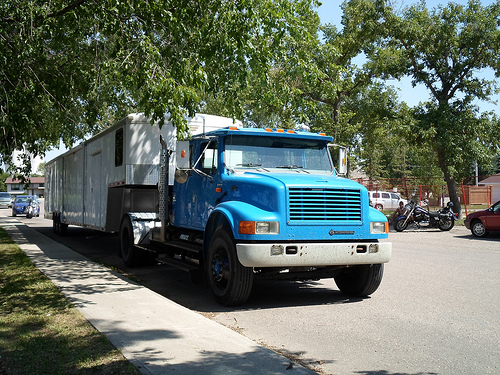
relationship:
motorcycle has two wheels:
[388, 181, 460, 238] [391, 210, 456, 233]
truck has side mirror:
[37, 109, 403, 313] [327, 140, 355, 178]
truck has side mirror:
[37, 109, 403, 313] [173, 136, 213, 180]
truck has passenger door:
[37, 109, 403, 313] [187, 139, 218, 231]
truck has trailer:
[37, 109, 403, 313] [41, 107, 252, 268]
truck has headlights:
[37, 109, 403, 313] [255, 216, 385, 239]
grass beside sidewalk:
[0, 225, 145, 375] [1, 227, 320, 375]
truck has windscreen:
[37, 109, 403, 313] [224, 134, 333, 173]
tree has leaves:
[330, 0, 499, 226] [324, 2, 498, 180]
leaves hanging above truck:
[1, 0, 331, 176] [37, 109, 403, 313]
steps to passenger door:
[155, 232, 203, 279] [187, 139, 218, 231]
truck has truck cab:
[37, 109, 403, 313] [172, 122, 397, 267]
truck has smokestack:
[37, 109, 403, 313] [156, 146, 174, 242]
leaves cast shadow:
[1, 0, 331, 176] [1, 233, 465, 375]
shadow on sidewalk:
[1, 233, 465, 375] [1, 227, 320, 375]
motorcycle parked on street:
[388, 181, 460, 238] [15, 196, 499, 374]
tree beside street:
[330, 0, 499, 226] [15, 196, 499, 374]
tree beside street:
[271, 21, 405, 228] [15, 196, 499, 374]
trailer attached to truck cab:
[41, 107, 252, 268] [172, 122, 397, 267]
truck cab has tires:
[172, 122, 397, 312] [201, 224, 388, 314]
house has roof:
[473, 173, 500, 204] [476, 169, 500, 185]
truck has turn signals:
[37, 109, 403, 313] [238, 221, 390, 235]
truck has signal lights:
[37, 109, 403, 313] [236, 218, 394, 236]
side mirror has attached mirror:
[173, 136, 213, 180] [170, 167, 193, 186]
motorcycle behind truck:
[20, 192, 45, 221] [37, 109, 403, 313]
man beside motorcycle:
[386, 198, 416, 226] [388, 181, 460, 238]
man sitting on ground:
[386, 198, 416, 226] [377, 200, 500, 229]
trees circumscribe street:
[0, 1, 500, 225] [15, 196, 499, 374]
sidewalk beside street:
[1, 227, 320, 375] [15, 196, 499, 374]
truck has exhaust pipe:
[37, 109, 403, 313] [154, 145, 175, 241]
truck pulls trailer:
[37, 109, 403, 313] [41, 107, 252, 268]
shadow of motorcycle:
[389, 225, 443, 237] [388, 181, 460, 238]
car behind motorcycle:
[459, 200, 499, 240] [388, 181, 460, 238]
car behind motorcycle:
[6, 193, 41, 219] [20, 192, 45, 221]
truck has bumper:
[37, 109, 403, 313] [232, 239, 395, 275]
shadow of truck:
[29, 221, 377, 316] [37, 109, 403, 313]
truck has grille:
[37, 109, 403, 313] [284, 181, 364, 225]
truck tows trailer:
[37, 109, 403, 313] [41, 107, 252, 268]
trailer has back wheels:
[41, 107, 252, 268] [51, 209, 70, 238]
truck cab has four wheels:
[172, 122, 397, 312] [111, 209, 389, 311]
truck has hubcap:
[37, 109, 403, 313] [207, 251, 228, 283]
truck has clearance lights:
[37, 109, 403, 313] [224, 125, 329, 137]